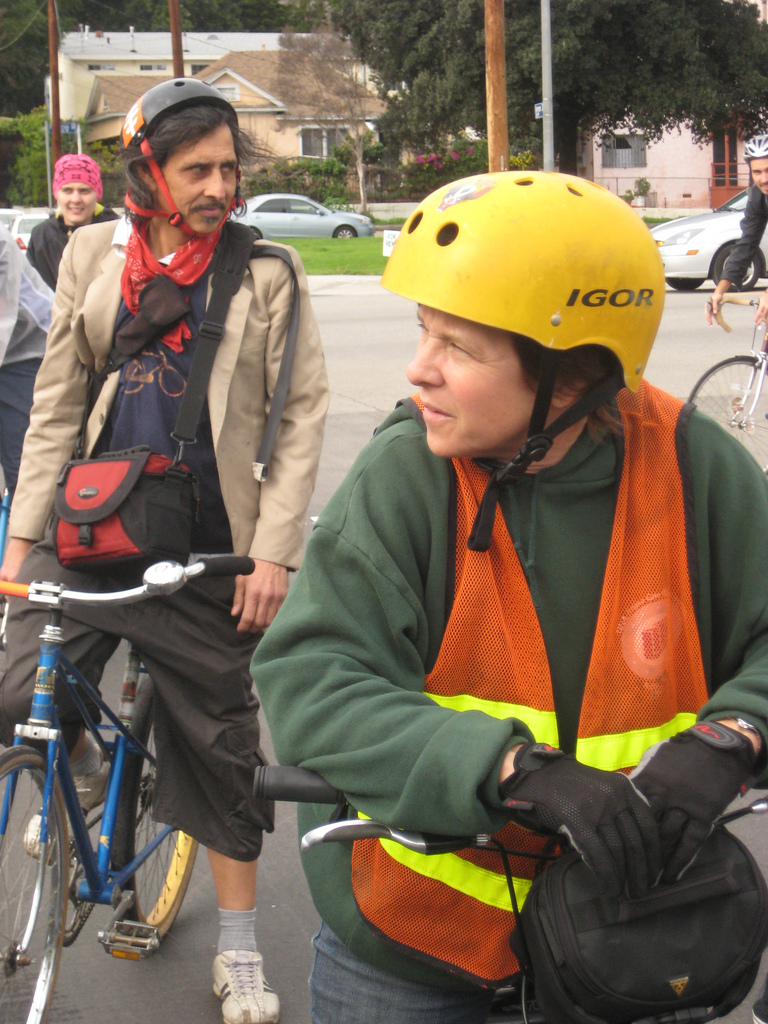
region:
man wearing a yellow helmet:
[370, 168, 666, 403]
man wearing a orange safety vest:
[387, 456, 715, 922]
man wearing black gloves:
[509, 714, 738, 880]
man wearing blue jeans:
[273, 914, 494, 1019]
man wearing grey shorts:
[2, 532, 269, 868]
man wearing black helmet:
[112, 75, 192, 147]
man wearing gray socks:
[209, 904, 270, 953]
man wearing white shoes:
[202, 941, 289, 1022]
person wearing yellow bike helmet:
[253, 175, 766, 1011]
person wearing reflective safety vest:
[256, 174, 763, 1019]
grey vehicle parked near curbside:
[224, 192, 376, 235]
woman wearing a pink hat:
[20, 155, 117, 289]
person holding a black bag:
[251, 167, 766, 1018]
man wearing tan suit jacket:
[0, 77, 323, 1012]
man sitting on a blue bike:
[0, 75, 332, 1020]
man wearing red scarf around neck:
[0, 76, 332, 1012]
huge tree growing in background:
[348, 0, 764, 232]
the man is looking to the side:
[58, 62, 277, 239]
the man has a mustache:
[172, 193, 240, 230]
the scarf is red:
[94, 202, 222, 325]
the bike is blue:
[1, 584, 201, 975]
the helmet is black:
[109, 64, 263, 251]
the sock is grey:
[194, 891, 282, 972]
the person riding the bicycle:
[250, 142, 759, 1021]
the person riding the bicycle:
[14, 52, 334, 1021]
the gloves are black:
[481, 723, 747, 902]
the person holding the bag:
[256, 163, 749, 1011]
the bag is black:
[499, 807, 765, 1022]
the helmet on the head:
[365, 165, 683, 389]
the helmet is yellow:
[365, 163, 661, 396]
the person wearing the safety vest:
[257, 168, 757, 1022]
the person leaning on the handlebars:
[256, 157, 766, 1010]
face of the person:
[115, 53, 233, 217]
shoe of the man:
[201, 919, 270, 1001]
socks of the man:
[194, 888, 276, 968]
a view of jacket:
[385, 849, 480, 974]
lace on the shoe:
[202, 917, 298, 1014]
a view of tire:
[23, 825, 94, 996]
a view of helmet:
[402, 202, 618, 367]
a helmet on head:
[357, 134, 659, 392]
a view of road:
[286, 871, 324, 976]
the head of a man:
[339, 146, 604, 457]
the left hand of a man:
[512, 738, 650, 892]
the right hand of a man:
[588, 719, 722, 863]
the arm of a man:
[283, 650, 549, 834]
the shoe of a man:
[211, 927, 299, 1020]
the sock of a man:
[192, 898, 296, 974]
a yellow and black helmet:
[373, 167, 676, 554]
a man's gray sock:
[218, 907, 260, 953]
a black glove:
[483, 746, 669, 901]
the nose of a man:
[405, 331, 449, 390]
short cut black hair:
[117, 105, 236, 186]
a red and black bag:
[55, 220, 267, 566]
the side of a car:
[227, 192, 380, 238]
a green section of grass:
[262, 229, 407, 270]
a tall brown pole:
[477, 0, 524, 184]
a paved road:
[284, 276, 766, 497]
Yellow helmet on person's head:
[357, 154, 682, 484]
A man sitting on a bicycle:
[0, 54, 352, 1015]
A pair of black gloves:
[486, 695, 760, 916]